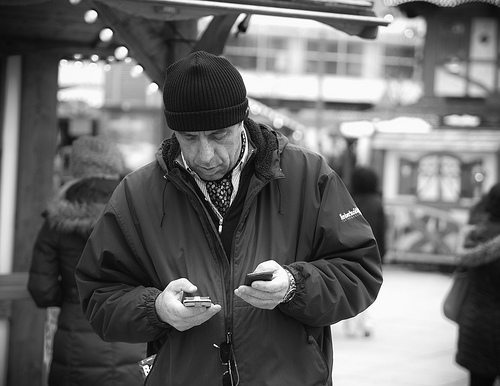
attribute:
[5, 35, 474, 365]
message — text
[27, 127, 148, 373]
jacket — winter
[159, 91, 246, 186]
head — man's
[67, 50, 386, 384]
man — looking down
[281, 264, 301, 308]
wrist — man's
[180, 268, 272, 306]
messages — his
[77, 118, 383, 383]
jacket — heavy, man's